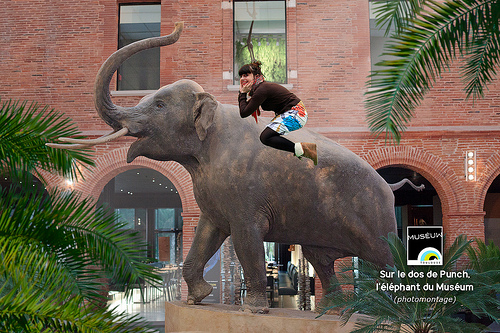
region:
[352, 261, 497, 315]
white writing on photograph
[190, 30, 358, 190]
person on elephant statue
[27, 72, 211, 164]
elephant with two large white tusks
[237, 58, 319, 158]
woman in colorful shorts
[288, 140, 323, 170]
woman with brown boots on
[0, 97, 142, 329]
large trees in photo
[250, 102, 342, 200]
woman with leggings on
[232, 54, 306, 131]
woman with brown shirt on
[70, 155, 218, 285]
arched doorway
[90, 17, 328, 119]
two windows in photograph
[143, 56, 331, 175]
Woman sitting on an elephant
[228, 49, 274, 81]
Woman has dark hair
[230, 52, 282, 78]
Woman's hair is brown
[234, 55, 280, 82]
Woman's hair is pulled back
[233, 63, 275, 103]
Woman's hands are holding her face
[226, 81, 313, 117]
Woman wearing brown shirt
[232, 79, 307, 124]
Woman's shirt has long sleeve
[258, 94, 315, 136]
Woman wearing multi colored shorts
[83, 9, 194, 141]
Elephants trunk is raised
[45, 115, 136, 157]
Elephant has two tusks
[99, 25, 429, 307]
statue of a elephant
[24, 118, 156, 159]
elephant has two tusks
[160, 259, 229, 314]
elephant lifting his foot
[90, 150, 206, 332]
doorway is arched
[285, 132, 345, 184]
girl wearing boots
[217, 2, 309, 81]
four tan bricks around window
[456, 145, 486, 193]
four lights on the building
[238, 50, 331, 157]
picture of girl on the elephant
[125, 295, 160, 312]
tiles on the floor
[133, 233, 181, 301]
tables in the building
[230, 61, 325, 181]
girl sitting on elephant statue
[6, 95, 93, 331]
Palm tree in front of building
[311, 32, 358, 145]
Building made of brick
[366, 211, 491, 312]
Advertisement for a museum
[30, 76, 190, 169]
Elephant statue has tusks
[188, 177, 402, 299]
Elephant statue is made of stone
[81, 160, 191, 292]
Entrance into the museum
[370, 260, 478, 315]
Advertisement is written in spanish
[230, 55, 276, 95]
Woman is wearing hair up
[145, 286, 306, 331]
Elephant statue is placed on a stone block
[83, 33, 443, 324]
large elephant statue in front of building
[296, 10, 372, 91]
multi colored brick wall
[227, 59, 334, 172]
woman posing on elephant statue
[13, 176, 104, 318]
lush green fern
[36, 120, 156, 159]
tusks of elephant statue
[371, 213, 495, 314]
museum logo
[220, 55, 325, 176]
woman wearing brown shirt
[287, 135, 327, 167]
furry white and brown boots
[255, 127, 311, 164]
black leggings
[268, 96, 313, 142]
white blue and orange skirt